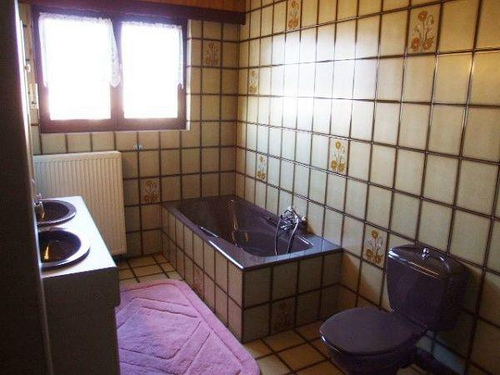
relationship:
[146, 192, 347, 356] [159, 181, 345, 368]
tile on tub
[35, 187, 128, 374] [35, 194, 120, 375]
sinks in sinks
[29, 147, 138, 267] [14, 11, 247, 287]
heater on wall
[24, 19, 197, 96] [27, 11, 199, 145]
curtains on windows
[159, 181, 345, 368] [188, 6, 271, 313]
tub in corner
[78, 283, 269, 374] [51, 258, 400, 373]
bathmat on floor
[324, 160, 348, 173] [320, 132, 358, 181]
flowers on tiles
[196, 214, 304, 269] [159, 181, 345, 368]
contours on tub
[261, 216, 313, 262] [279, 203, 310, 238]
hose on faucet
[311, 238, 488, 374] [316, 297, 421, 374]
toilet has seat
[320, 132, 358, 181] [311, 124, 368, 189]
tiles with print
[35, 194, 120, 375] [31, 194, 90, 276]
sinks has double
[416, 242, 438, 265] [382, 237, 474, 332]
flush on top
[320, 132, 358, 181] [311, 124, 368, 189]
tiles have print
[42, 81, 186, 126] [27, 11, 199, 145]
sun through windows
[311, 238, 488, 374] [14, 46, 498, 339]
toilet in bathroom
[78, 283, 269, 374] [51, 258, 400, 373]
rug on floor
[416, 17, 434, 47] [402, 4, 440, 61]
pattern on tile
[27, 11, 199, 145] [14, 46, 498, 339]
window in bathroom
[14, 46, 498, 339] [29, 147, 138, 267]
bathroom has radiator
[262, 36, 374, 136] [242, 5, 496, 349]
light on wall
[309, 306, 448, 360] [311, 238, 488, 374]
lid of toilet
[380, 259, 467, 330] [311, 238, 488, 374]
back of toilet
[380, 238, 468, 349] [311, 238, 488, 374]
tank on toilet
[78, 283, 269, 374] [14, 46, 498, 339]
rug in bathroom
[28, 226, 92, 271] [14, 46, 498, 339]
sink for bathroom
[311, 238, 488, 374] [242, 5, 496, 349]
toilet on wall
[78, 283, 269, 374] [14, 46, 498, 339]
carpet in bathroom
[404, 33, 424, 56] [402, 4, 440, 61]
flower on tile